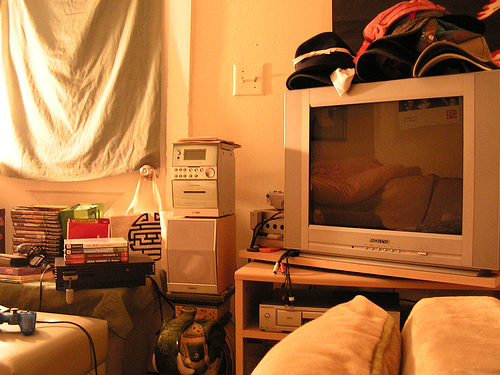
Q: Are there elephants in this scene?
A: Yes, there is an elephant.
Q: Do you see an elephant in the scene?
A: Yes, there is an elephant.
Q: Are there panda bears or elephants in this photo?
A: Yes, there is an elephant.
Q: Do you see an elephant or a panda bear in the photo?
A: Yes, there is an elephant.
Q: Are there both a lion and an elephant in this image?
A: No, there is an elephant but no lions.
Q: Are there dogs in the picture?
A: No, there are no dogs.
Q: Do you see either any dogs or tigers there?
A: No, there are no dogs or tigers.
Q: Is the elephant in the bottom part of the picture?
A: Yes, the elephant is in the bottom of the image.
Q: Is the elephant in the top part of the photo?
A: No, the elephant is in the bottom of the image.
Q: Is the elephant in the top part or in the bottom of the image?
A: The elephant is in the bottom of the image.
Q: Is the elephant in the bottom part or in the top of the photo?
A: The elephant is in the bottom of the image.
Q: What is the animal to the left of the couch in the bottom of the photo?
A: The animal is an elephant.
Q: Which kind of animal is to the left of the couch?
A: The animal is an elephant.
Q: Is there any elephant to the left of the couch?
A: Yes, there is an elephant to the left of the couch.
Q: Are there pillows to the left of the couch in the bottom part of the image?
A: No, there is an elephant to the left of the couch.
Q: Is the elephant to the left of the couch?
A: Yes, the elephant is to the left of the couch.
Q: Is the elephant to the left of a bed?
A: No, the elephant is to the left of the couch.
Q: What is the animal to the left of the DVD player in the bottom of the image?
A: The animal is an elephant.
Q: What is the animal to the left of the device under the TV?
A: The animal is an elephant.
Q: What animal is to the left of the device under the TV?
A: The animal is an elephant.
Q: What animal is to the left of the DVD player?
A: The animal is an elephant.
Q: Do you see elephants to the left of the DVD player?
A: Yes, there is an elephant to the left of the DVD player.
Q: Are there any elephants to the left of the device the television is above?
A: Yes, there is an elephant to the left of the DVD player.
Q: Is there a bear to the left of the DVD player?
A: No, there is an elephant to the left of the DVD player.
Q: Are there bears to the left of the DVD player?
A: No, there is an elephant to the left of the DVD player.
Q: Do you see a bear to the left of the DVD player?
A: No, there is an elephant to the left of the DVD player.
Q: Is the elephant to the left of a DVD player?
A: Yes, the elephant is to the left of a DVD player.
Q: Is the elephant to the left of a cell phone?
A: No, the elephant is to the left of a DVD player.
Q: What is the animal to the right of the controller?
A: The animal is an elephant.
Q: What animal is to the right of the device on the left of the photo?
A: The animal is an elephant.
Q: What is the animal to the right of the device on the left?
A: The animal is an elephant.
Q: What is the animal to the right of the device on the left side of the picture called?
A: The animal is an elephant.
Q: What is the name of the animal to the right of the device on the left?
A: The animal is an elephant.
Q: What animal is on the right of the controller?
A: The animal is an elephant.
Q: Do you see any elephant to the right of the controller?
A: Yes, there is an elephant to the right of the controller.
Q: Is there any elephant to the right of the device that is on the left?
A: Yes, there is an elephant to the right of the controller.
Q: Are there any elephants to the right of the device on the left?
A: Yes, there is an elephant to the right of the controller.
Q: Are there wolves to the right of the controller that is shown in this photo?
A: No, there is an elephant to the right of the controller.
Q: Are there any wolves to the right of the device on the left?
A: No, there is an elephant to the right of the controller.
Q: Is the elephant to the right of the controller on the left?
A: Yes, the elephant is to the right of the controller.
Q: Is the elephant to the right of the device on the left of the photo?
A: Yes, the elephant is to the right of the controller.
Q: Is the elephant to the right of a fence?
A: No, the elephant is to the right of the controller.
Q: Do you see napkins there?
A: No, there are no napkins.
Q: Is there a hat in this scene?
A: Yes, there is a hat.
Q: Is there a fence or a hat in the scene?
A: Yes, there is a hat.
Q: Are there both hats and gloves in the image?
A: No, there is a hat but no gloves.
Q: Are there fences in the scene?
A: No, there are no fences.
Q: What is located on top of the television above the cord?
A: The hat is on top of the TV.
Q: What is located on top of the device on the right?
A: The hat is on top of the TV.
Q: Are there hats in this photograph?
A: Yes, there is a hat.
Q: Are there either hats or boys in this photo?
A: Yes, there is a hat.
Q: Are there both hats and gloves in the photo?
A: No, there is a hat but no gloves.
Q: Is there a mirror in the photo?
A: No, there are no mirrors.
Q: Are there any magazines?
A: No, there are no magazines.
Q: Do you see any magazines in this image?
A: No, there are no magazines.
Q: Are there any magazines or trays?
A: No, there are no magazines or trays.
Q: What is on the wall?
A: The light switch is on the wall.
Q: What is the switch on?
A: The switch is on the wall.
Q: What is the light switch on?
A: The switch is on the wall.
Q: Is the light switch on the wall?
A: Yes, the light switch is on the wall.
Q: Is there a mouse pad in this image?
A: No, there are no mouse pads.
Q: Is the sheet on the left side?
A: Yes, the sheet is on the left of the image.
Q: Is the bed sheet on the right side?
A: No, the bed sheet is on the left of the image.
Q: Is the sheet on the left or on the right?
A: The sheet is on the left of the image.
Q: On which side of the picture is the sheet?
A: The sheet is on the left of the image.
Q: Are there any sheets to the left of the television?
A: Yes, there is a sheet to the left of the television.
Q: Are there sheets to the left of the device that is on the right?
A: Yes, there is a sheet to the left of the television.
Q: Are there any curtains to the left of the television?
A: No, there is a sheet to the left of the television.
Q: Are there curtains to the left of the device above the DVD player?
A: No, there is a sheet to the left of the television.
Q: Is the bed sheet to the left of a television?
A: Yes, the bed sheet is to the left of a television.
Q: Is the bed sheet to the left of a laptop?
A: No, the bed sheet is to the left of a television.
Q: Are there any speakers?
A: Yes, there is a speaker.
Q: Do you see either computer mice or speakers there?
A: Yes, there is a speaker.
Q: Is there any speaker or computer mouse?
A: Yes, there is a speaker.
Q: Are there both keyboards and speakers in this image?
A: No, there is a speaker but no keyboards.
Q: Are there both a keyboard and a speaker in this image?
A: No, there is a speaker but no keyboards.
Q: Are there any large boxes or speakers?
A: Yes, there is a large speaker.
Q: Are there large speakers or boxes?
A: Yes, there is a large speaker.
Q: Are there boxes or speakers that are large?
A: Yes, the speaker is large.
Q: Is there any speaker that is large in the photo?
A: Yes, there is a large speaker.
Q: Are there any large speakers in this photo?
A: Yes, there is a large speaker.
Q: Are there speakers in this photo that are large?
A: Yes, there is a speaker that is large.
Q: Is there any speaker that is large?
A: Yes, there is a speaker that is large.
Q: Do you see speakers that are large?
A: Yes, there is a speaker that is large.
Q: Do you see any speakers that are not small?
A: Yes, there is a large speaker.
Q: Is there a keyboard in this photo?
A: No, there are no keyboards.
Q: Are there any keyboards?
A: No, there are no keyboards.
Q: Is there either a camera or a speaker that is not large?
A: No, there is a speaker but it is large.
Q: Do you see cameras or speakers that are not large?
A: No, there is a speaker but it is large.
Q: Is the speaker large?
A: Yes, the speaker is large.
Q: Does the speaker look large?
A: Yes, the speaker is large.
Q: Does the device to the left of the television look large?
A: Yes, the speaker is large.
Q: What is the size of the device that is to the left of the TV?
A: The speaker is large.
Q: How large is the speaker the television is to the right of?
A: The speaker is large.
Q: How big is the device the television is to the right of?
A: The speaker is large.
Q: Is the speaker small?
A: No, the speaker is large.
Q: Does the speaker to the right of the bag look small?
A: No, the speaker is large.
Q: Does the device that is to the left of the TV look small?
A: No, the speaker is large.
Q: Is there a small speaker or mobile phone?
A: No, there is a speaker but it is large.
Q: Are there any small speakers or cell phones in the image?
A: No, there is a speaker but it is large.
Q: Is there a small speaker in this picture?
A: No, there is a speaker but it is large.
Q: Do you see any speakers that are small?
A: No, there is a speaker but it is large.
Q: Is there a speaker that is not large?
A: No, there is a speaker but it is large.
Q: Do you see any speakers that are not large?
A: No, there is a speaker but it is large.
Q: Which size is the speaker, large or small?
A: The speaker is large.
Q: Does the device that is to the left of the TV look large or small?
A: The speaker is large.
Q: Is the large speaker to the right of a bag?
A: Yes, the speaker is to the right of a bag.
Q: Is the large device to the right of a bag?
A: Yes, the speaker is to the right of a bag.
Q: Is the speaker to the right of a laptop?
A: No, the speaker is to the right of a bag.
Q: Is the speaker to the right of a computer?
A: No, the speaker is to the right of the bag.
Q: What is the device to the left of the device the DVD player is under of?
A: The device is a speaker.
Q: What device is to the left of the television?
A: The device is a speaker.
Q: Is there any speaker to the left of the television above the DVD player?
A: Yes, there is a speaker to the left of the TV.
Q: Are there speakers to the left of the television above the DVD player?
A: Yes, there is a speaker to the left of the TV.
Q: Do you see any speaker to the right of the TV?
A: No, the speaker is to the left of the TV.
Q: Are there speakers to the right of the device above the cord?
A: No, the speaker is to the left of the TV.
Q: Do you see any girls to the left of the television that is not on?
A: No, there is a speaker to the left of the television.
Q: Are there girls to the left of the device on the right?
A: No, there is a speaker to the left of the television.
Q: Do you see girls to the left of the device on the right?
A: No, there is a speaker to the left of the television.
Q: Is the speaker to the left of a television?
A: Yes, the speaker is to the left of a television.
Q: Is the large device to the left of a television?
A: Yes, the speaker is to the left of a television.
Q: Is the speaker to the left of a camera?
A: No, the speaker is to the left of a television.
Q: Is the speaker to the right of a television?
A: No, the speaker is to the left of a television.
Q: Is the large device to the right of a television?
A: No, the speaker is to the left of a television.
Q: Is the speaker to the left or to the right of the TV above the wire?
A: The speaker is to the left of the television.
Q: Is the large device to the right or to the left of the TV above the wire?
A: The speaker is to the left of the television.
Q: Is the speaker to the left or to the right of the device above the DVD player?
A: The speaker is to the left of the television.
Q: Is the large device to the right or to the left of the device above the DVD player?
A: The speaker is to the left of the television.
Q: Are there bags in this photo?
A: Yes, there is a bag.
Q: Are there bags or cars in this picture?
A: Yes, there is a bag.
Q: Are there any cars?
A: No, there are no cars.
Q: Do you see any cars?
A: No, there are no cars.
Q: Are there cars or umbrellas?
A: No, there are no cars or umbrellas.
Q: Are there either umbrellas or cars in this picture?
A: No, there are no cars or umbrellas.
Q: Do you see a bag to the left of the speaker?
A: Yes, there is a bag to the left of the speaker.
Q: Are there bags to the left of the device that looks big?
A: Yes, there is a bag to the left of the speaker.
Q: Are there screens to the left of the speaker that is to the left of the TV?
A: No, there is a bag to the left of the speaker.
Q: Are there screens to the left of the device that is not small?
A: No, there is a bag to the left of the speaker.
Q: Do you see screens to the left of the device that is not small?
A: No, there is a bag to the left of the speaker.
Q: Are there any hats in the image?
A: Yes, there is a hat.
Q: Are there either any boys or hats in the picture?
A: Yes, there is a hat.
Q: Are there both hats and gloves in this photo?
A: No, there is a hat but no gloves.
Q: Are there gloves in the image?
A: No, there are no gloves.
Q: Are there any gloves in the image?
A: No, there are no gloves.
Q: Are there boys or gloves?
A: No, there are no gloves or boys.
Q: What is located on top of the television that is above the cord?
A: The hat is on top of the television.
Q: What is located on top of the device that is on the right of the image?
A: The hat is on top of the television.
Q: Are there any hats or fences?
A: Yes, there is a hat.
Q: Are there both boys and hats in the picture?
A: No, there is a hat but no boys.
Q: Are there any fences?
A: No, there are no fences.